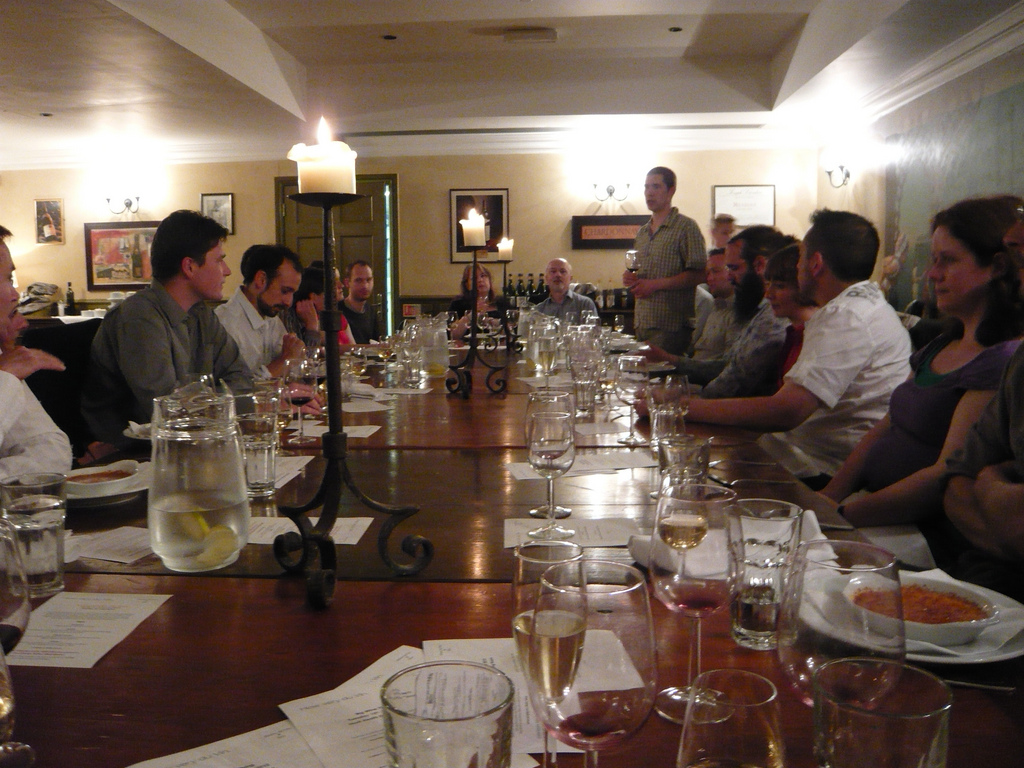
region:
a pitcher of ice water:
[139, 367, 267, 587]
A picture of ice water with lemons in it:
[139, 363, 258, 586]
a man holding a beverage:
[619, 164, 717, 336]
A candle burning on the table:
[271, 102, 434, 611]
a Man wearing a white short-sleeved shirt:
[776, 203, 898, 464]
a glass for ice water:
[522, 404, 589, 526]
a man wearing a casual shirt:
[91, 205, 248, 387]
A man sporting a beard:
[716, 216, 783, 330]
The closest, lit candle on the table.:
[285, 113, 359, 205]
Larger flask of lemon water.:
[145, 417, 250, 573]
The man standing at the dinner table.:
[625, 165, 708, 347]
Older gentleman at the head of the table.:
[527, 259, 598, 321]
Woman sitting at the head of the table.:
[448, 266, 510, 321]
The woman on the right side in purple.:
[822, 195, 1012, 541]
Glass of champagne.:
[659, 474, 710, 548]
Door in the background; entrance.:
[271, 174, 402, 258]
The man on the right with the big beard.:
[726, 225, 785, 318]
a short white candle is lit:
[284, 123, 361, 197]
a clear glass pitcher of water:
[136, 386, 253, 580]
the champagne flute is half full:
[511, 534, 591, 766]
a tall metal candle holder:
[258, 180, 435, 608]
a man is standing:
[619, 160, 708, 366]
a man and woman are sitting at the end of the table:
[443, 255, 596, 341]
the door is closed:
[269, 168, 402, 339]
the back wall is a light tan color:
[0, 136, 826, 307]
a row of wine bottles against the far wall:
[490, 265, 552, 308]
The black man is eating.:
[247, 440, 599, 643]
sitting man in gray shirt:
[84, 211, 258, 406]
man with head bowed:
[210, 245, 306, 381]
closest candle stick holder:
[273, 191, 430, 612]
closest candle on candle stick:
[281, 108, 358, 194]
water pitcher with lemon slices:
[148, 367, 253, 570]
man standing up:
[622, 165, 706, 356]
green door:
[269, 171, 400, 345]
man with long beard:
[702, 224, 792, 405]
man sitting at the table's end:
[528, 256, 602, 326]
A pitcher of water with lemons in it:
[133, 367, 261, 580]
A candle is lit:
[270, 99, 370, 204]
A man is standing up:
[610, 152, 718, 359]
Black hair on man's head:
[137, 200, 237, 306]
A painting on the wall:
[71, 209, 177, 299]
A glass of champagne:
[500, 525, 596, 760]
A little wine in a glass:
[640, 474, 762, 741]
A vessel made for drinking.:
[521, 411, 592, 558]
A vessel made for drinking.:
[716, 475, 814, 657]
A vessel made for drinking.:
[638, 468, 718, 617]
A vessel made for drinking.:
[654, 430, 719, 528]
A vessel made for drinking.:
[132, 406, 287, 574]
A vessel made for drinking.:
[369, 650, 531, 762]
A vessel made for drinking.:
[648, 653, 784, 759]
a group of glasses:
[474, 437, 996, 764]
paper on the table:
[13, 557, 217, 700]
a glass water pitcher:
[118, 373, 275, 592]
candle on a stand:
[244, 70, 444, 601]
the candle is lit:
[288, 119, 369, 203]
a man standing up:
[598, 157, 717, 350]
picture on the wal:
[63, 209, 163, 299]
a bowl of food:
[813, 544, 1010, 678]